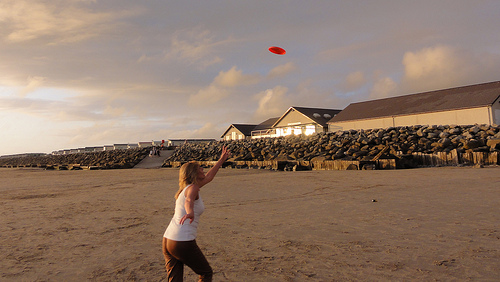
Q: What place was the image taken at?
A: It was taken at the beach.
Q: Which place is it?
A: It is a beach.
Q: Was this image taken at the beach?
A: Yes, it was taken in the beach.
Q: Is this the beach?
A: Yes, it is the beach.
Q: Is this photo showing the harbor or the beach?
A: It is showing the beach.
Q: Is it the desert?
A: No, it is the beach.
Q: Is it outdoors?
A: Yes, it is outdoors.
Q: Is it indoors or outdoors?
A: It is outdoors.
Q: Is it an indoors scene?
A: No, it is outdoors.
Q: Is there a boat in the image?
A: No, there are no boats.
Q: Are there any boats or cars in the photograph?
A: No, there are no boats or cars.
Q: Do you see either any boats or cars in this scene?
A: No, there are no boats or cars.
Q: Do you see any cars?
A: No, there are no cars.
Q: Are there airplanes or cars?
A: No, there are no cars or airplanes.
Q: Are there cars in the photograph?
A: No, there are no cars.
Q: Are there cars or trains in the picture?
A: No, there are no cars or trains.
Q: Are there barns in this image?
A: No, there are no barns.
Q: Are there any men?
A: No, there are no men.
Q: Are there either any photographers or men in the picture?
A: No, there are no men or photographers.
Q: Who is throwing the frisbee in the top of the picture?
A: The girl is throwing the frisbee.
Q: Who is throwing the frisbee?
A: The girl is throwing the frisbee.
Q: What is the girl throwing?
A: The girl is throwing the frisbee.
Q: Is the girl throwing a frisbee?
A: Yes, the girl is throwing a frisbee.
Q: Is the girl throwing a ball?
A: No, the girl is throwing a frisbee.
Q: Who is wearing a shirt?
A: The girl is wearing a shirt.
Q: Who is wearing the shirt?
A: The girl is wearing a shirt.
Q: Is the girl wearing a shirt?
A: Yes, the girl is wearing a shirt.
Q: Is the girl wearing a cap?
A: No, the girl is wearing a shirt.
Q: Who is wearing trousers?
A: The girl is wearing trousers.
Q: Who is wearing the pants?
A: The girl is wearing trousers.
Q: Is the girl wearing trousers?
A: Yes, the girl is wearing trousers.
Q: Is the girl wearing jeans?
A: No, the girl is wearing trousers.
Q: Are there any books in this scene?
A: No, there are no books.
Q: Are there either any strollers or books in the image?
A: No, there are no books or strollers.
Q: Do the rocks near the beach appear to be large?
A: Yes, the rocks are large.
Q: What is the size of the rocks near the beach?
A: The rocks are large.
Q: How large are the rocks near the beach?
A: The rocks are large.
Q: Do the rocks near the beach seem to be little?
A: No, the rocks are large.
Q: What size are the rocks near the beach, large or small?
A: The rocks are large.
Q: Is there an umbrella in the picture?
A: No, there are no umbrellas.